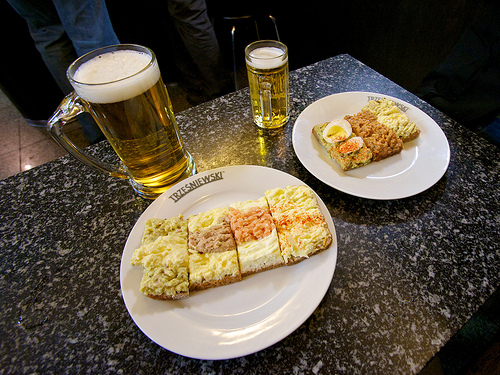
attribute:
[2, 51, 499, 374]
counter — granite, black, white, speckled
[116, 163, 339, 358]
plate — white, shiny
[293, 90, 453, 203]
plate — white, small, shiny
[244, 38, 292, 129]
mug — filled, small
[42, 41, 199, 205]
mug — filled, large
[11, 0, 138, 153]
jeans — blue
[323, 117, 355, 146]
egg — deviled, hardboiled, broken, halved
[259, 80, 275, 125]
handle — glass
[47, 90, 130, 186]
handle — glass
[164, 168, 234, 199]
writing — black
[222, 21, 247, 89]
leg — metal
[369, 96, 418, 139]
cake — sliced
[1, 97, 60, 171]
floor — tile